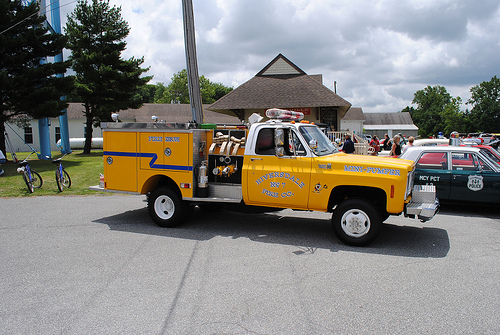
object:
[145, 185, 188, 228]
tire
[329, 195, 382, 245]
tire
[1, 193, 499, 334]
road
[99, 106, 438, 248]
truck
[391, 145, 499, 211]
car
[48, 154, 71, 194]
bicycle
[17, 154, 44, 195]
bicycle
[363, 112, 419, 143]
building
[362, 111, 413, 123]
roof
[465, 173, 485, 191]
police logo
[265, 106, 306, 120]
light bar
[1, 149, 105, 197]
grass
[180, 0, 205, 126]
ladder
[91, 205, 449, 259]
shadow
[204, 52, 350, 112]
roof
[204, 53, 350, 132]
building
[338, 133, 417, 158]
people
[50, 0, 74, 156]
pole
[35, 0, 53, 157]
pole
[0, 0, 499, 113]
sky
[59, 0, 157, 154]
tree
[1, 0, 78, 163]
tree